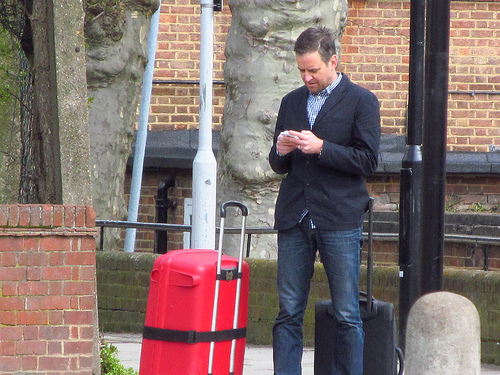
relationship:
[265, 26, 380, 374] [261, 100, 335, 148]
man texting on cellphone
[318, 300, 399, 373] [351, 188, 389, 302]
suitcase with handle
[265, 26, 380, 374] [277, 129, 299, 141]
man holding cellphone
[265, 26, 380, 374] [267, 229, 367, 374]
man wearing blue jeans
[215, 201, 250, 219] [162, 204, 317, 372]
black handle of a suitcase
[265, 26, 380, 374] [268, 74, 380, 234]
man wearing jacket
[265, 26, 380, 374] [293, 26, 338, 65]
man with brown hair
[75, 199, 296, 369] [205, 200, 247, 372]
suitcase with a metal handle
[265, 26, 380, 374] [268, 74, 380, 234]
man wearing a jacket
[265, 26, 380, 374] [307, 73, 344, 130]
man wearing a shirt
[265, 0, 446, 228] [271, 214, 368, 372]
man wearing blue jeans